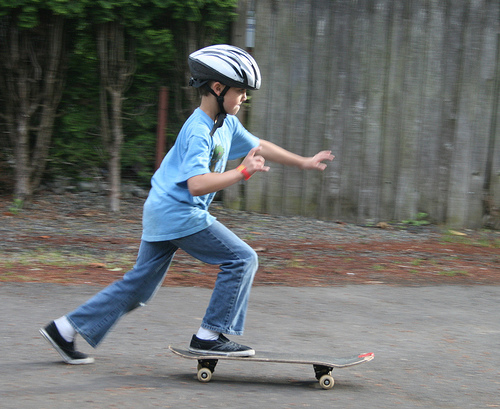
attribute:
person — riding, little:
[30, 29, 385, 385]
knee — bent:
[215, 229, 271, 292]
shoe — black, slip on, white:
[28, 317, 106, 370]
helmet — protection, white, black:
[165, 40, 274, 131]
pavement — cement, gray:
[381, 324, 490, 408]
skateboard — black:
[161, 325, 378, 393]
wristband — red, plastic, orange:
[227, 159, 262, 184]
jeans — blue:
[56, 215, 264, 365]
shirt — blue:
[138, 109, 269, 239]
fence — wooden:
[272, 19, 496, 142]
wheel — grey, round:
[188, 362, 219, 385]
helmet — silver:
[159, 18, 279, 108]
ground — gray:
[308, 291, 449, 338]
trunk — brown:
[4, 83, 57, 205]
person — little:
[29, 33, 339, 371]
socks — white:
[50, 312, 220, 344]